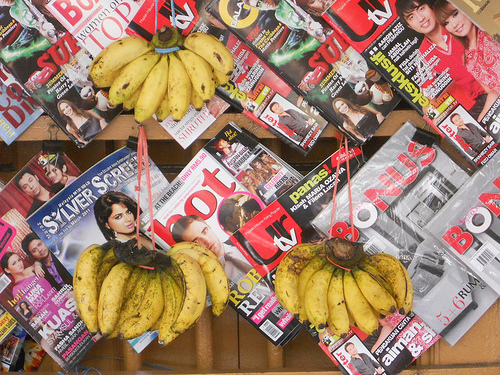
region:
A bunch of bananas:
[270, 240, 410, 337]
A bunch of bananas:
[89, 28, 234, 120]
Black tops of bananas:
[105, 243, 162, 271]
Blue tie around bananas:
[150, 45, 189, 51]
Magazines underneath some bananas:
[0, 119, 498, 372]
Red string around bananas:
[132, 130, 156, 249]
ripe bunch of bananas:
[273, 238, 412, 335]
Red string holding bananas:
[322, 129, 360, 273]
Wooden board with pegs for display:
[1, 107, 494, 143]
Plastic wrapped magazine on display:
[310, 120, 495, 347]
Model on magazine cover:
[91, 189, 150, 246]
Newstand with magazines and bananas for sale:
[2, 2, 498, 372]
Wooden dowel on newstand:
[187, 140, 214, 371]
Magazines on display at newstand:
[1, 126, 495, 373]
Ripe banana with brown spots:
[274, 240, 325, 319]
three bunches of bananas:
[23, 32, 418, 335]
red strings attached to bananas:
[131, 126, 360, 248]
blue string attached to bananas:
[149, 0, 182, 54]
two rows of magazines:
[3, 6, 499, 366]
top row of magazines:
[3, 4, 498, 167]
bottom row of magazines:
[8, 150, 499, 367]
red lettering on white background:
[148, 162, 239, 250]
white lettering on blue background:
[40, 152, 148, 242]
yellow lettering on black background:
[373, 44, 441, 121]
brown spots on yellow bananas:
[289, 228, 403, 323]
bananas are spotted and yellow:
[73, 241, 228, 347]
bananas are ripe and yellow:
[276, 240, 416, 337]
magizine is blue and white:
[24, 144, 196, 355]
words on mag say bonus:
[336, 138, 438, 246]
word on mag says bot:
[147, 169, 239, 249]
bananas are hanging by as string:
[89, 29, 238, 124]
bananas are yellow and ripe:
[86, 26, 235, 125]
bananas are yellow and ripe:
[71, 238, 230, 347]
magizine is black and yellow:
[206, 1, 409, 141]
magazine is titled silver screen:
[23, 144, 211, 357]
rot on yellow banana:
[68, 228, 100, 332]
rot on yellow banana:
[104, 273, 124, 341]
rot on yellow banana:
[134, 272, 171, 327]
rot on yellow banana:
[172, 275, 202, 337]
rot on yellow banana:
[205, 258, 235, 313]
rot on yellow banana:
[271, 238, 311, 305]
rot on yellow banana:
[352, 269, 412, 331]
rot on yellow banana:
[187, 59, 225, 104]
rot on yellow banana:
[100, 32, 120, 84]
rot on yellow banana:
[100, 72, 140, 103]